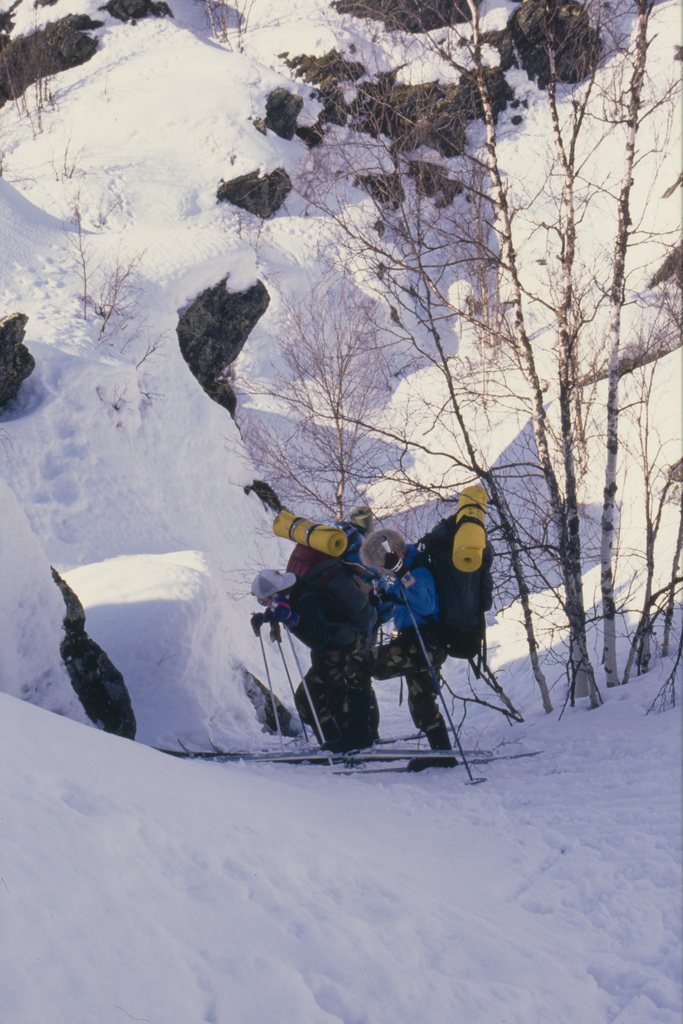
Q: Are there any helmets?
A: No, there are no helmets.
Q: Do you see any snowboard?
A: No, there are no snowboards.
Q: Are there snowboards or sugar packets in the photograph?
A: No, there are no snowboards or sugar packets.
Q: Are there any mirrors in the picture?
A: No, there are no mirrors.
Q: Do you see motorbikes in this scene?
A: No, there are no motorbikes.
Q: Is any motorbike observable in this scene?
A: No, there are no motorcycles.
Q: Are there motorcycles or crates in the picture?
A: No, there are no motorcycles or crates.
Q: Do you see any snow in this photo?
A: Yes, there is snow.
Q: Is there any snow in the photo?
A: Yes, there is snow.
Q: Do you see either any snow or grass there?
A: Yes, there is snow.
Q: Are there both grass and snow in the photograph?
A: No, there is snow but no grass.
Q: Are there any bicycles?
A: No, there are no bicycles.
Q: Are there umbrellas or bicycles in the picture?
A: No, there are no bicycles or umbrellas.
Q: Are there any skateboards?
A: No, there are no skateboards.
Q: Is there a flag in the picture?
A: No, there are no flags.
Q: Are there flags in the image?
A: No, there are no flags.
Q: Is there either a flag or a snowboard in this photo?
A: No, there are no flags or snowboards.